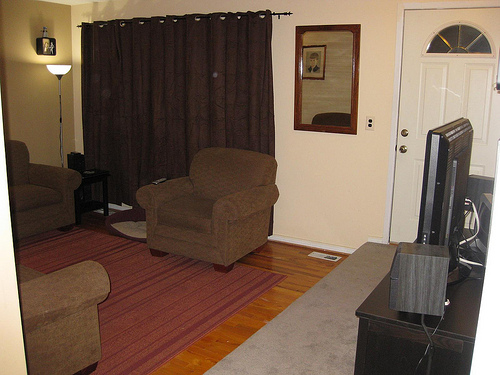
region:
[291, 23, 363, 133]
Framed mirror hangs on the wall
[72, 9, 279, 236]
Curtains close off the window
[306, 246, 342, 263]
White air vent in the floor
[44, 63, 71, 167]
Floor lamp is on in the corner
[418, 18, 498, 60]
Arched window in the door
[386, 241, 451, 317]
Speaker on the stand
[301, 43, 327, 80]
Picture reflected in the mirro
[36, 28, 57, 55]
Oleo situated on the wall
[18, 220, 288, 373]
Red are rug on the floor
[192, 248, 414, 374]
Gray carpet in the entryway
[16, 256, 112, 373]
one of three brown living room chairs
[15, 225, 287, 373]
mauve striped living room rug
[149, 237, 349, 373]
brown wood living room floor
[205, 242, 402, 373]
light gray living room rug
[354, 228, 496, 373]
black piece of furniture supporting a flat screen television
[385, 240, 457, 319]
speaker sitting next to a flat screen television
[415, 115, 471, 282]
black flat screen television in an average living room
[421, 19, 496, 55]
semi-circle window high in a cream color door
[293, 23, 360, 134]
wood frame mirror hanging on a living room wall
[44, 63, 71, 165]
turned on living room floor lamp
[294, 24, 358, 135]
Mirror hanging on the wall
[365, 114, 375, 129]
Light switch in the wall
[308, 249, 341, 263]
Heater vent in the floor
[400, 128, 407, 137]
Deadbolt to lock the door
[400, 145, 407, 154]
Doorknob on the door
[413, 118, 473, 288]
Flatscreen display sitting on countertop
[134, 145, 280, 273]
Plush chair with armrests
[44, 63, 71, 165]
Floor lamp sitting in the corner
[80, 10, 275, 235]
Brown drapes hanging in the window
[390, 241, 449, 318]
Small speaker sitting on a countertop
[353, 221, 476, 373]
A black entertainment center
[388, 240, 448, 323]
A black speaker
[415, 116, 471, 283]
A large black television on the entertainment center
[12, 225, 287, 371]
A maroon colored rug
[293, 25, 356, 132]
A mirror on the wall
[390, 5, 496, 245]
A white door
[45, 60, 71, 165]
A floor lamp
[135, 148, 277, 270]
a large brown seat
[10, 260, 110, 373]
a large brown seat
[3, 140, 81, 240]
a large brown seat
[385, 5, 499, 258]
Cream colored front door.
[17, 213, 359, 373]
Striped carpet on wooden floor.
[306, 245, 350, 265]
Floor vent in wooden floor.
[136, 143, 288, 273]
Brown cloth arm chair.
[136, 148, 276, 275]
Wooden legs on arm chair.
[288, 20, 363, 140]
Dark brown wood framed mirror.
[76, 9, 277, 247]
Dark brown curtains to match.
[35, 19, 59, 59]
Small shadow box on wall.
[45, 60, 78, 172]
Floor lamp that is lit.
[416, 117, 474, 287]
Black and silver flat screen television.